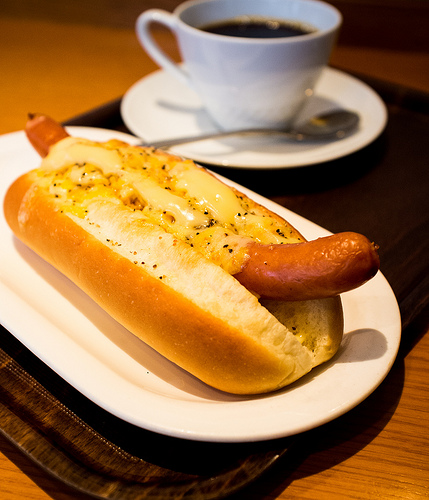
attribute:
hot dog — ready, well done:
[3, 107, 385, 404]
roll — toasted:
[2, 139, 348, 398]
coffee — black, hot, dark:
[193, 13, 320, 42]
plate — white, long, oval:
[1, 122, 408, 450]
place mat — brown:
[1, 57, 428, 499]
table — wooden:
[2, 0, 429, 499]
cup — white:
[132, 0, 343, 147]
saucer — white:
[115, 58, 391, 175]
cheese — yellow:
[38, 133, 281, 281]